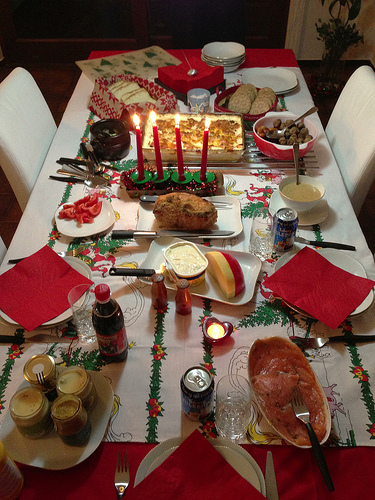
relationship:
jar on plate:
[9, 385, 51, 440] [3, 362, 129, 470]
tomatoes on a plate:
[59, 194, 102, 226] [54, 199, 116, 241]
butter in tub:
[167, 243, 206, 276] [161, 240, 209, 287]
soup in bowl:
[280, 182, 321, 204] [277, 174, 327, 213]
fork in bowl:
[289, 386, 336, 491] [246, 331, 334, 449]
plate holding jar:
[3, 362, 129, 470] [9, 385, 51, 440]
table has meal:
[1, 47, 374, 498] [11, 73, 332, 450]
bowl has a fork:
[251, 110, 318, 161] [289, 386, 336, 491]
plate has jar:
[3, 362, 129, 470] [9, 385, 51, 440]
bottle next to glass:
[92, 284, 128, 363] [68, 282, 101, 353]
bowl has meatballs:
[251, 110, 318, 161] [256, 118, 312, 146]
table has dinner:
[1, 47, 374, 498] [11, 73, 332, 450]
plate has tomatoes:
[54, 199, 116, 241] [59, 194, 102, 226]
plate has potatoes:
[246, 331, 334, 449] [250, 340, 326, 445]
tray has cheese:
[133, 234, 265, 307] [203, 251, 247, 300]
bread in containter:
[108, 79, 155, 104] [88, 71, 180, 133]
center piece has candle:
[120, 111, 223, 200] [131, 115, 149, 184]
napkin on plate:
[2, 245, 99, 325] [0, 258, 93, 328]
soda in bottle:
[92, 299, 130, 362] [92, 284, 128, 363]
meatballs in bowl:
[256, 118, 312, 146] [251, 110, 318, 161]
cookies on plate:
[229, 84, 274, 116] [212, 83, 278, 121]